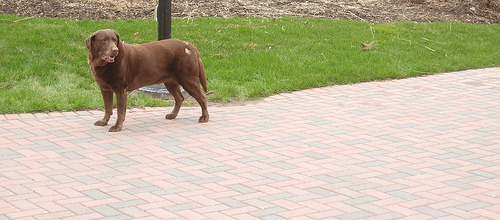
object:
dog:
[84, 27, 210, 132]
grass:
[201, 22, 497, 66]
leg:
[94, 87, 113, 126]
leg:
[108, 85, 128, 131]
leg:
[163, 79, 184, 121]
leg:
[186, 76, 209, 123]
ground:
[1, 66, 499, 219]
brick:
[240, 158, 276, 171]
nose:
[112, 47, 119, 54]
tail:
[198, 56, 209, 93]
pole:
[157, 1, 171, 42]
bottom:
[136, 82, 192, 101]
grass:
[1, 1, 498, 24]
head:
[85, 29, 122, 63]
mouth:
[101, 53, 118, 61]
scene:
[1, 1, 499, 220]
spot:
[181, 40, 190, 46]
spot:
[184, 46, 191, 55]